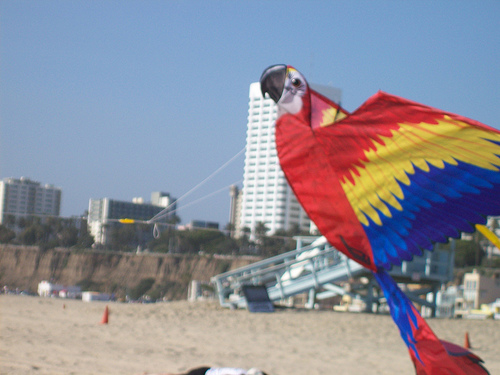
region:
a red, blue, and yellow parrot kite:
[252, 56, 496, 373]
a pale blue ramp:
[214, 228, 378, 313]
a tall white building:
[233, 72, 348, 254]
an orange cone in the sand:
[95, 296, 115, 326]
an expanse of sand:
[1, 293, 498, 372]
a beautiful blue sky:
[1, 2, 498, 229]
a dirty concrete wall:
[2, 241, 272, 306]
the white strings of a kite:
[135, 110, 293, 238]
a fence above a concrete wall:
[0, 218, 294, 252]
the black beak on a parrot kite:
[257, 62, 290, 103]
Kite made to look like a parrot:
[252, 42, 499, 339]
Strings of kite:
[125, 194, 192, 239]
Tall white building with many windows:
[249, 89, 288, 221]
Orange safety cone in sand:
[93, 304, 123, 329]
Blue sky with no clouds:
[0, 15, 202, 130]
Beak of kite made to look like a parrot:
[261, 67, 286, 98]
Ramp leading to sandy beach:
[229, 254, 345, 294]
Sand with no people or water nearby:
[144, 310, 376, 358]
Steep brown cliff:
[9, 248, 188, 288]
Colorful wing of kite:
[339, 97, 469, 237]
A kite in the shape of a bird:
[234, 51, 498, 373]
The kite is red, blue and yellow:
[244, 46, 499, 373]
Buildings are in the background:
[1, 42, 337, 237]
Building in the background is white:
[225, 72, 346, 233]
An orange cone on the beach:
[92, 300, 123, 330]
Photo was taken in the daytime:
[7, 7, 490, 372]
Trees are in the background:
[3, 212, 289, 265]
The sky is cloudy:
[0, 4, 499, 134]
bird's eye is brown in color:
[286, 73, 306, 93]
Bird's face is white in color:
[278, 61, 310, 116]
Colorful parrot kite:
[221, 48, 475, 373]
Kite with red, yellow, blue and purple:
[208, 28, 480, 367]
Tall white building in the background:
[216, 56, 371, 266]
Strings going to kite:
[121, 108, 271, 276]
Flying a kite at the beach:
[73, 23, 463, 372]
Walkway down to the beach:
[191, 207, 471, 334]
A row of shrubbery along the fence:
[9, 199, 304, 273]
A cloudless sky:
[10, 4, 258, 189]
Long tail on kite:
[303, 231, 488, 373]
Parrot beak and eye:
[247, 51, 313, 113]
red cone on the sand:
[79, 295, 129, 328]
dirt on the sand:
[153, 307, 284, 351]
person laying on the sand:
[176, 348, 281, 371]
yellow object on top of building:
[119, 210, 159, 230]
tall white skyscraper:
[231, 68, 282, 230]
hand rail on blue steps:
[203, 256, 328, 281]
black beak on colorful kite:
[225, 56, 309, 110]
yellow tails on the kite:
[340, 125, 428, 197]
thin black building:
[222, 180, 240, 227]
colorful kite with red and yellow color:
[256, 55, 483, 340]